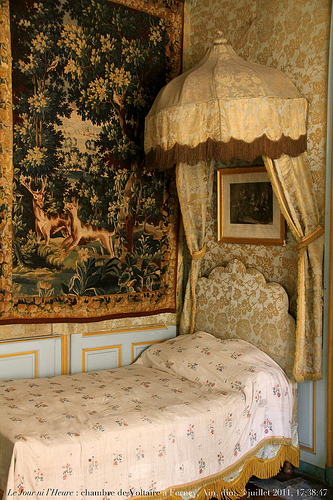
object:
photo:
[213, 164, 283, 246]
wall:
[181, 2, 332, 480]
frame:
[216, 164, 284, 247]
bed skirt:
[138, 420, 300, 496]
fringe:
[166, 436, 302, 500]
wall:
[0, 0, 181, 377]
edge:
[72, 317, 174, 340]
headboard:
[181, 259, 300, 379]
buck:
[17, 172, 73, 247]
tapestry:
[3, 1, 185, 327]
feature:
[142, 28, 310, 174]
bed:
[0, 259, 297, 499]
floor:
[211, 467, 331, 500]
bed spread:
[0, 329, 293, 500]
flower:
[216, 362, 226, 375]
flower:
[39, 431, 51, 442]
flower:
[134, 445, 144, 463]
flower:
[80, 391, 89, 401]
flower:
[226, 414, 235, 428]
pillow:
[144, 328, 276, 395]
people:
[258, 189, 271, 215]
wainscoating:
[0, 321, 179, 380]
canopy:
[144, 30, 325, 385]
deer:
[60, 201, 117, 261]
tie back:
[293, 220, 322, 250]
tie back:
[187, 238, 209, 260]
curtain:
[262, 138, 322, 383]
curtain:
[172, 145, 209, 335]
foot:
[0, 426, 27, 500]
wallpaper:
[185, 2, 329, 340]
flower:
[78, 247, 87, 262]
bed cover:
[1, 330, 295, 496]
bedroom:
[1, 1, 333, 499]